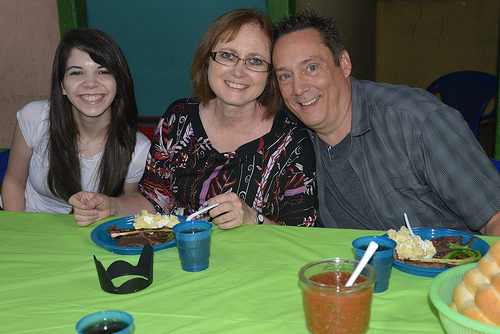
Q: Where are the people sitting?
A: At a table.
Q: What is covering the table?
A: A tablecloth.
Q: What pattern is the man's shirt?
A: Plaid.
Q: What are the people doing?
A: Eating.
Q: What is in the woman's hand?
A: A fork..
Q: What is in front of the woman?
A: A plate.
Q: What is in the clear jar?
A: Salsa.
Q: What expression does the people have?
A: Smiles.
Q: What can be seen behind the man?
A: Chair back.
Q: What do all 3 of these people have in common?
A: Smiling.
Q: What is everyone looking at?
A: The camera.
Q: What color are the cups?
A: Blue.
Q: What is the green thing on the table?
A: Tablecloth.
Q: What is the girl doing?
A: Smiling.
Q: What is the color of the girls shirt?
A: White.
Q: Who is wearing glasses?
A: The lady in the middle.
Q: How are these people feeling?
A: Happy.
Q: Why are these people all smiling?
A: For pictures.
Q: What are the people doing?
A: Smiling for a photo.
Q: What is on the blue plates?
A: Food.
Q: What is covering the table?
A: Green table cloth.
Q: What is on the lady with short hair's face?
A: Glasses.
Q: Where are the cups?
A: On the table.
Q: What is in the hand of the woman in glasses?
A: A utensil.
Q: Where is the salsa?
A: In a container.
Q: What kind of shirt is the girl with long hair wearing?
A: T shirt.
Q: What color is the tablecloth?
A: Green.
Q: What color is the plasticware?
A: Blue.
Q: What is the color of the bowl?
A: Green.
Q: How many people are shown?
A: Three.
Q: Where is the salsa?
A: Container.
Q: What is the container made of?
A: Plastic.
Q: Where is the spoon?
A: In salsa.